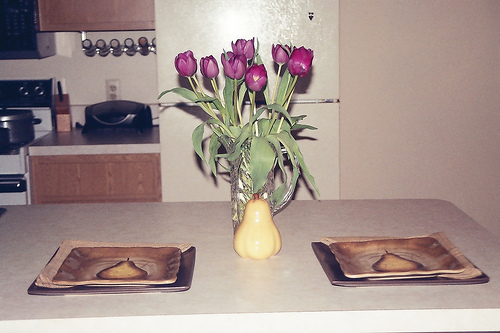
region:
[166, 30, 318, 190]
vase of flowers on a table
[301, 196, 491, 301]
plate on a table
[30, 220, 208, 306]
plate on a table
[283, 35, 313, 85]
flower in a vase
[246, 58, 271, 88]
flower in a vase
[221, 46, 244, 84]
flower in a vase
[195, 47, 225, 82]
flower in a vase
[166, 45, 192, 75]
flower in a vase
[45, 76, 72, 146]
knife on a counter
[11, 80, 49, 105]
knobs on a stove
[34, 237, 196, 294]
Brown plate with pear print on it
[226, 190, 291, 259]
Yellow pear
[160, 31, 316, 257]
Vase of purple flowers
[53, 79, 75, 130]
Wooden block for knives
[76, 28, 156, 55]
Spice rack with multiple different spices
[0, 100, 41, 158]
Pot on top of stove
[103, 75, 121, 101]
Electric outlet on wall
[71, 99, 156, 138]
Black cd player unplugged from wall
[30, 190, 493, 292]
Two matching pear plates and a pear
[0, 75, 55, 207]
Kitchen stove with pot on top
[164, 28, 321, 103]
the tulips are purple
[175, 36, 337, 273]
flower vase on the counter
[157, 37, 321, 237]
Purple flower stems in a glass vase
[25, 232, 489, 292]
Two matching sets of plate and napkins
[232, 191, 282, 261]
Fake yellow pear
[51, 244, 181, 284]
Square plate with a pear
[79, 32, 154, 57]
Rack hanging under a cabinet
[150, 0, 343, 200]
White two door refrigerator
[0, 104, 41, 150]
Large silver cooking pot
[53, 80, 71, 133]
Wood knife holder with a single knife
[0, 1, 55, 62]
Black microwave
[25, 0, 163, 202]
Wood cabinets with no handles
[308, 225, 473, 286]
plate on right side of table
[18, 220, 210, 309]
plate on left side of table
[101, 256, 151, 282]
pear in left plate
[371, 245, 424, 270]
pear in right plate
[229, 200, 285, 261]
vegetable vase on table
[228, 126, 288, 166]
leaves under roses in vase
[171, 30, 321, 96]
roses sprouting out of vase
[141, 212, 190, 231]
top of large table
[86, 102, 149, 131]
black gorge forman grill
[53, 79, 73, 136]
knife in knife holder